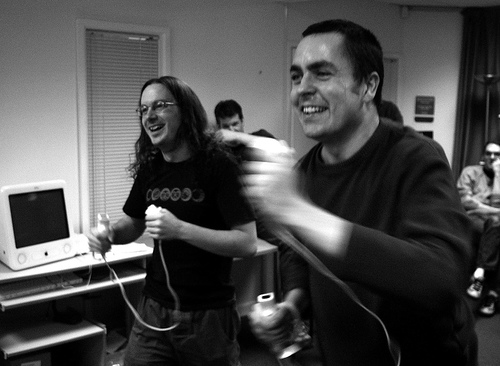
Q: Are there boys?
A: No, there are no boys.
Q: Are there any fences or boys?
A: No, there are no boys or fences.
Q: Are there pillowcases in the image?
A: No, there are no pillowcases.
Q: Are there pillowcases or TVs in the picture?
A: No, there are no pillowcases or tvs.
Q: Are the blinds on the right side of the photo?
A: No, the blinds are on the left of the image.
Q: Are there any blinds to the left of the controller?
A: Yes, there are blinds to the left of the controller.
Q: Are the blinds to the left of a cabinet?
A: No, the blinds are to the left of a controller.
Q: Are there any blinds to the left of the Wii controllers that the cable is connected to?
A: Yes, there are blinds to the left of the Wii controllers.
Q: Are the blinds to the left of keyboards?
A: No, the blinds are to the left of the Wii remotes.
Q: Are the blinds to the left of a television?
A: No, the blinds are to the left of a man.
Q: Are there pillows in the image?
A: No, there are no pillows.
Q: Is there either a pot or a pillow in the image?
A: No, there are no pillows or pots.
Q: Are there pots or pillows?
A: No, there are no pillows or pots.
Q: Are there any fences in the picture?
A: No, there are no fences.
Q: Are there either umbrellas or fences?
A: No, there are no fences or umbrellas.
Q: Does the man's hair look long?
A: Yes, the hair is long.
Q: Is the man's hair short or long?
A: The hair is long.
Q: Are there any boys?
A: No, there are no boys.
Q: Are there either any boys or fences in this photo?
A: No, there are no boys or fences.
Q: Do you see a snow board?
A: No, there are no snowboards.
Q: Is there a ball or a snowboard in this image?
A: No, there are no snowboards or balls.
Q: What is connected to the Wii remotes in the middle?
A: The cable is connected to the Wii remotes.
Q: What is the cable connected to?
A: The cable is connected to the Wii remotes.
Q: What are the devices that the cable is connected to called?
A: The devices are Wii controllers.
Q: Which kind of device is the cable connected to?
A: The cable is connected to the Wii controllers.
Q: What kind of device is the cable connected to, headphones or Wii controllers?
A: The cable is connected to Wii controllers.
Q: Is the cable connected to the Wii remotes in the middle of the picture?
A: Yes, the cable is connected to the Wii remotes.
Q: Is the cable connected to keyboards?
A: No, the cable is connected to the Wii remotes.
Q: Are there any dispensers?
A: No, there are no dispensers.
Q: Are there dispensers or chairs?
A: No, there are no dispensers or chairs.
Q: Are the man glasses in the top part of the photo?
A: Yes, the glasses are in the top of the image.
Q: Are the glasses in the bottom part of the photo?
A: No, the glasses are in the top of the image.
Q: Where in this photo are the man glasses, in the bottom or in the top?
A: The glasses are in the top of the image.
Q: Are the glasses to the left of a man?
A: Yes, the glasses are to the left of a man.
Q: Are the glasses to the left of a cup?
A: No, the glasses are to the left of a man.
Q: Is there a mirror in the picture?
A: No, there are no mirrors.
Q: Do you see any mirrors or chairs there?
A: No, there are no mirrors or chairs.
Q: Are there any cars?
A: No, there are no cars.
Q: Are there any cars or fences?
A: No, there are no cars or fences.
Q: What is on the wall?
A: The sign is on the wall.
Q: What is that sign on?
A: The sign is on the wall.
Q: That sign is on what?
A: The sign is on the wall.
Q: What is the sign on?
A: The sign is on the wall.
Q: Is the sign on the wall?
A: Yes, the sign is on the wall.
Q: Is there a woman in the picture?
A: No, there are no women.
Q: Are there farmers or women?
A: No, there are no women or farmers.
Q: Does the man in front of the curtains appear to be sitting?
A: Yes, the man is sitting.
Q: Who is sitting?
A: The man is sitting.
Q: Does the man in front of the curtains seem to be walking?
A: No, the man is sitting.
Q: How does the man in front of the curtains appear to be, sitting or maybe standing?
A: The man is sitting.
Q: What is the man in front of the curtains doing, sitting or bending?
A: The man is sitting.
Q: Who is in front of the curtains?
A: The man is in front of the curtains.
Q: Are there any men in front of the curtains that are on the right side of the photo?
A: Yes, there is a man in front of the curtains.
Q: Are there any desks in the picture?
A: Yes, there is a desk.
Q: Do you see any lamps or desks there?
A: Yes, there is a desk.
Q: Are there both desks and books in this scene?
A: No, there is a desk but no books.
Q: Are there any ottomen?
A: No, there are no ottomen.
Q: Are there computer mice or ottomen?
A: No, there are no ottomen or computer mice.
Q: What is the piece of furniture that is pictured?
A: The piece of furniture is a desk.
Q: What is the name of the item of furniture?
A: The piece of furniture is a desk.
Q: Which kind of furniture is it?
A: The piece of furniture is a desk.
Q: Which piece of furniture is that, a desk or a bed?
A: That is a desk.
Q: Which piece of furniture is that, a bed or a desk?
A: That is a desk.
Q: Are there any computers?
A: Yes, there is a computer.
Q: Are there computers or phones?
A: Yes, there is a computer.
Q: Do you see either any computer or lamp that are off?
A: Yes, the computer is off.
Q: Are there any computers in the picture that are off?
A: Yes, there is a computer that is off.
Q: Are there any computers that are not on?
A: Yes, there is a computer that is off.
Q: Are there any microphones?
A: No, there are no microphones.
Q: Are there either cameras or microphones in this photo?
A: No, there are no microphones or cameras.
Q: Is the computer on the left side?
A: Yes, the computer is on the left of the image.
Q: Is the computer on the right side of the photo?
A: No, the computer is on the left of the image.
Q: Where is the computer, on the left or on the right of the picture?
A: The computer is on the left of the image.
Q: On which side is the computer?
A: The computer is on the left of the image.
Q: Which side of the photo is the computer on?
A: The computer is on the left of the image.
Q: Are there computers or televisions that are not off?
A: No, there is a computer but it is off.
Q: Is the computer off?
A: Yes, the computer is off.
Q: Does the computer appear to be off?
A: Yes, the computer is off.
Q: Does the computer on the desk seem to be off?
A: Yes, the computer is off.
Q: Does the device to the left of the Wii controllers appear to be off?
A: Yes, the computer is off.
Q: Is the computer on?
A: No, the computer is off.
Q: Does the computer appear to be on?
A: No, the computer is off.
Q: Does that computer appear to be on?
A: No, the computer is off.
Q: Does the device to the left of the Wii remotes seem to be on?
A: No, the computer is off.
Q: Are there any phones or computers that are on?
A: No, there is a computer but it is off.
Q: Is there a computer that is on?
A: No, there is a computer but it is off.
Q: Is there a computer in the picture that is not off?
A: No, there is a computer but it is off.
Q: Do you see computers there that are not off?
A: No, there is a computer but it is off.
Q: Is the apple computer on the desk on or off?
A: The computer is off.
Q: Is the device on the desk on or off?
A: The computer is off.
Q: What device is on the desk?
A: The device is a computer.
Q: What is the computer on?
A: The computer is on the desk.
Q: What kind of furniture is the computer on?
A: The computer is on the desk.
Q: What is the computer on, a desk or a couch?
A: The computer is on a desk.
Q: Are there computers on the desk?
A: Yes, there is a computer on the desk.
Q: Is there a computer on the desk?
A: Yes, there is a computer on the desk.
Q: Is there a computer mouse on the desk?
A: No, there is a computer on the desk.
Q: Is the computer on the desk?
A: Yes, the computer is on the desk.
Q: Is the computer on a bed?
A: No, the computer is on the desk.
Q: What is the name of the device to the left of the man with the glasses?
A: The device is a computer.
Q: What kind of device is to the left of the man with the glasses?
A: The device is a computer.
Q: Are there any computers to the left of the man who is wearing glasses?
A: Yes, there is a computer to the left of the man.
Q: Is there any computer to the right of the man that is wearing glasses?
A: No, the computer is to the left of the man.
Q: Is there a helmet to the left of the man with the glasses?
A: No, there is a computer to the left of the man.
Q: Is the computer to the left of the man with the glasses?
A: Yes, the computer is to the left of the man.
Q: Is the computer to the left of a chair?
A: No, the computer is to the left of the man.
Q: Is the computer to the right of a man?
A: No, the computer is to the left of a man.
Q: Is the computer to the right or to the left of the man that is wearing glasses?
A: The computer is to the left of the man.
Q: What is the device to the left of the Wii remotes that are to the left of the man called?
A: The device is a computer.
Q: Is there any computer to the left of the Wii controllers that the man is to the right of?
A: Yes, there is a computer to the left of the Wii controllers.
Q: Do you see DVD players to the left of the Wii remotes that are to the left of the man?
A: No, there is a computer to the left of the Wii controllers.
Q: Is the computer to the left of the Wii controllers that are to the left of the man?
A: Yes, the computer is to the left of the Wii controllers.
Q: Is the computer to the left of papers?
A: No, the computer is to the left of the Wii controllers.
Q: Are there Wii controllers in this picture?
A: Yes, there are Wii controllers.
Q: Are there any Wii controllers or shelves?
A: Yes, there are Wii controllers.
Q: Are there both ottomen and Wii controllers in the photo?
A: No, there are Wii controllers but no ottomen.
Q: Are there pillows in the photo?
A: No, there are no pillows.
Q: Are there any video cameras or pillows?
A: No, there are no pillows or video cameras.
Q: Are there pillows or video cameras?
A: No, there are no pillows or video cameras.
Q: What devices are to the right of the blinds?
A: The devices are Wii controllers.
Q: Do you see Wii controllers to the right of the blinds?
A: Yes, there are Wii controllers to the right of the blinds.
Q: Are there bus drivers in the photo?
A: No, there are no bus drivers.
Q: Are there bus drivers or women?
A: No, there are no bus drivers or women.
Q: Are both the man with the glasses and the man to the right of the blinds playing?
A: Yes, both the man and the man are playing.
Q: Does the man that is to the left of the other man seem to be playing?
A: Yes, the man is playing.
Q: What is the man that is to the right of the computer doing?
A: The man is playing.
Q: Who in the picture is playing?
A: The man is playing.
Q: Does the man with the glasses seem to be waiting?
A: No, the man is playing.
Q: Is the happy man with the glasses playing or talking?
A: The man is playing.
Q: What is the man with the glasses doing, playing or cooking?
A: The man is playing.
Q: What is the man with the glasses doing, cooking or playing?
A: The man is playing.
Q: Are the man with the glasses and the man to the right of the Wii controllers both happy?
A: Yes, both the man and the man are happy.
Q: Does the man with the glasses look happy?
A: Yes, the man is happy.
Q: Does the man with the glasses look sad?
A: No, the man is happy.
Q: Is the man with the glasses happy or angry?
A: The man is happy.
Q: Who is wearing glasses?
A: The man is wearing glasses.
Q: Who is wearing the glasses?
A: The man is wearing glasses.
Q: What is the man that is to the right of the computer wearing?
A: The man is wearing glasses.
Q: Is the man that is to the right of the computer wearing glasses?
A: Yes, the man is wearing glasses.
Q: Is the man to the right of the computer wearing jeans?
A: No, the man is wearing glasses.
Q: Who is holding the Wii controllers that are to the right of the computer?
A: The man is holding the Wii controllers.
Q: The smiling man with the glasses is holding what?
A: The man is holding the Wii remotes.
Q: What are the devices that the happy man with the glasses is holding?
A: The devices are Wii controllers.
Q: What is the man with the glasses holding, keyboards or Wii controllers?
A: The man is holding Wii controllers.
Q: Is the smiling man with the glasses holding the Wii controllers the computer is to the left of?
A: Yes, the man is holding the Wii controllers.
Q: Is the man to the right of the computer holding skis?
A: No, the man is holding the Wii controllers.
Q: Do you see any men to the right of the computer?
A: Yes, there is a man to the right of the computer.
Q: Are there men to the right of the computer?
A: Yes, there is a man to the right of the computer.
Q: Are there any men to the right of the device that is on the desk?
A: Yes, there is a man to the right of the computer.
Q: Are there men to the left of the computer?
A: No, the man is to the right of the computer.